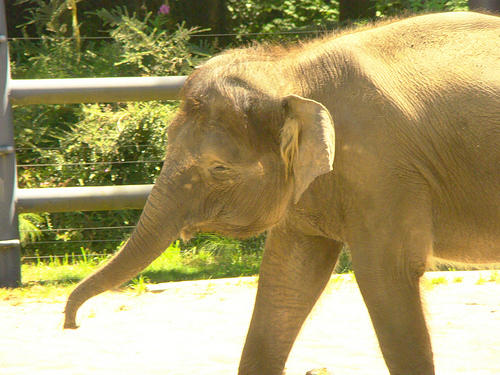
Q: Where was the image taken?
A: It was taken at the pen.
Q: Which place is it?
A: It is a pen.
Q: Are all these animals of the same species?
A: Yes, all the animals are elephants.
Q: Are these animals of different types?
A: No, all the animals are elephants.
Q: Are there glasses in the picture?
A: No, there are no glasses.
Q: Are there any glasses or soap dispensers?
A: No, there are no glasses or soap dispensers.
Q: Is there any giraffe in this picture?
A: No, there are no giraffes.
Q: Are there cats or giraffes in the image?
A: No, there are no giraffes or cats.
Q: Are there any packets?
A: No, there are no packets.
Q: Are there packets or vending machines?
A: No, there are no packets or vending machines.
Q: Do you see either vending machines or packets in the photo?
A: No, there are no packets or vending machines.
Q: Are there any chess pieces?
A: No, there are no chess pieces.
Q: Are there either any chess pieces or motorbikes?
A: No, there are no chess pieces or motorbikes.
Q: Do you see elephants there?
A: Yes, there is an elephant.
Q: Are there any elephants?
A: Yes, there is an elephant.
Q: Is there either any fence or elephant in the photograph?
A: Yes, there is an elephant.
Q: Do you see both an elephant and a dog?
A: No, there is an elephant but no dogs.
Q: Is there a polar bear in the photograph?
A: No, there are no polar bears.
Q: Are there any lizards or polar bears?
A: No, there are no polar bears or lizards.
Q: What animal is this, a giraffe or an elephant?
A: This is an elephant.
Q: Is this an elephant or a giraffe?
A: This is an elephant.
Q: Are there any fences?
A: Yes, there is a fence.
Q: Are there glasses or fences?
A: Yes, there is a fence.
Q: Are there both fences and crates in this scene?
A: No, there is a fence but no crates.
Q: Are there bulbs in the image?
A: No, there are no bulbs.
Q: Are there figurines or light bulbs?
A: No, there are no light bulbs or figurines.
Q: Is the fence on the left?
A: Yes, the fence is on the left of the image.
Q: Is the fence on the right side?
A: No, the fence is on the left of the image.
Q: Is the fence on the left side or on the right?
A: The fence is on the left of the image.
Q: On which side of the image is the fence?
A: The fence is on the left of the image.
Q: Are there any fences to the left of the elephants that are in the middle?
A: Yes, there is a fence to the left of the elephants.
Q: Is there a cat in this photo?
A: No, there are no cats.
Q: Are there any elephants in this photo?
A: Yes, there are elephants.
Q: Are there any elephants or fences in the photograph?
A: Yes, there are elephants.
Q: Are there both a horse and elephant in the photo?
A: No, there are elephants but no horses.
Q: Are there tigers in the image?
A: No, there are no tigers.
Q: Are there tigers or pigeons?
A: No, there are no tigers or pigeons.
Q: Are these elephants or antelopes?
A: These are elephants.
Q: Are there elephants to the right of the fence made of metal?
A: Yes, there are elephants to the right of the fence.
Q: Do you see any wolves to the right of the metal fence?
A: No, there are elephants to the right of the fence.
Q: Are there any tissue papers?
A: No, there are no tissue papers.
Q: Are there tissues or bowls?
A: No, there are no tissues or bowls.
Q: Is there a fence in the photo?
A: Yes, there is a fence.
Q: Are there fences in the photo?
A: Yes, there is a fence.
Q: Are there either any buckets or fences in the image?
A: Yes, there is a fence.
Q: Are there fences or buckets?
A: Yes, there is a fence.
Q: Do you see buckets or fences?
A: Yes, there is a fence.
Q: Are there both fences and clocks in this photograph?
A: No, there is a fence but no clocks.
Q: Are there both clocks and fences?
A: No, there is a fence but no clocks.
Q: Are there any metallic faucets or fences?
A: Yes, there is a metal fence.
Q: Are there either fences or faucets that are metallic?
A: Yes, the fence is metallic.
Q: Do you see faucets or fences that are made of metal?
A: Yes, the fence is made of metal.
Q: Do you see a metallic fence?
A: Yes, there is a metal fence.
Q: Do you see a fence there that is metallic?
A: Yes, there is a fence that is metallic.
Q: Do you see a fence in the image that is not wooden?
A: Yes, there is a metallic fence.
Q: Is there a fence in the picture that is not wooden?
A: Yes, there is a metallic fence.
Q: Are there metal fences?
A: Yes, there is a fence that is made of metal.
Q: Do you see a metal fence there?
A: Yes, there is a fence that is made of metal.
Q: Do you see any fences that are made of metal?
A: Yes, there is a fence that is made of metal.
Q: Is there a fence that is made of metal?
A: Yes, there is a fence that is made of metal.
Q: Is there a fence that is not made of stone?
A: Yes, there is a fence that is made of metal.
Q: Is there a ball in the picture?
A: No, there are no balls.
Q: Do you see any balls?
A: No, there are no balls.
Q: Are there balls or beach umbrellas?
A: No, there are no balls or beach umbrellas.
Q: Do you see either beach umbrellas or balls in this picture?
A: No, there are no balls or beach umbrellas.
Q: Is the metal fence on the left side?
A: Yes, the fence is on the left of the image.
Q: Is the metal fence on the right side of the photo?
A: No, the fence is on the left of the image.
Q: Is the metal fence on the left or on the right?
A: The fence is on the left of the image.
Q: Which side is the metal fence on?
A: The fence is on the left of the image.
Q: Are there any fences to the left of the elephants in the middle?
A: Yes, there is a fence to the left of the elephants.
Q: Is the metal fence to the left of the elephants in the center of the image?
A: Yes, the fence is to the left of the elephants.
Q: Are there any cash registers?
A: No, there are no cash registers.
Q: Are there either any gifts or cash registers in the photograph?
A: No, there are no cash registers or gifts.